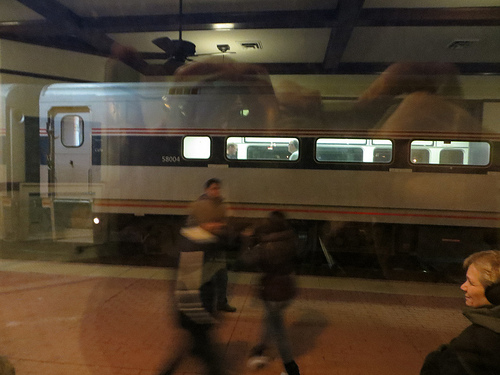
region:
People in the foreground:
[158, 170, 333, 372]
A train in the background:
[22, 75, 497, 276]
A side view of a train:
[27, 72, 497, 262]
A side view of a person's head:
[450, 245, 495, 315]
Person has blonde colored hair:
[445, 245, 495, 280]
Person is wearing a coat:
[401, 305, 496, 370]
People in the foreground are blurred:
[137, 176, 317, 371]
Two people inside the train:
[225, 137, 300, 162]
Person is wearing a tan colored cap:
[161, 190, 246, 242]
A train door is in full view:
[44, 104, 106, 211]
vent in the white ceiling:
[442, 34, 482, 60]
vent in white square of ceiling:
[145, 26, 315, 63]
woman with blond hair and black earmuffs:
[451, 248, 496, 318]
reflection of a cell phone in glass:
[152, 236, 232, 336]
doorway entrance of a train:
[41, 95, 106, 247]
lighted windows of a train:
[171, 113, 493, 177]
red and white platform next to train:
[17, 251, 472, 365]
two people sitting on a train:
[219, 134, 301, 165]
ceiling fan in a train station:
[114, 16, 244, 91]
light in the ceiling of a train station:
[198, 13, 250, 43]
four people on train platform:
[155, 164, 497, 359]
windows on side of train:
[177, 125, 479, 172]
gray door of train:
[47, 114, 89, 199]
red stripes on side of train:
[85, 118, 495, 226]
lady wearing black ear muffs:
[421, 250, 498, 370]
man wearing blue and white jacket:
[172, 180, 242, 370]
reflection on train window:
[42, 30, 492, 373]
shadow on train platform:
[247, 278, 334, 362]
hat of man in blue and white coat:
[180, 195, 219, 220]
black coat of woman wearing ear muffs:
[419, 319, 499, 373]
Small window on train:
[171, 126, 216, 166]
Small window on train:
[219, 129, 302, 168]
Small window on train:
[309, 133, 394, 173]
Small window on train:
[404, 126, 499, 175]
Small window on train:
[56, 115, 85, 149]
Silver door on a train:
[40, 102, 109, 246]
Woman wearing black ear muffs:
[446, 249, 498, 307]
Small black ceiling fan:
[120, 21, 216, 73]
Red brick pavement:
[45, 290, 80, 350]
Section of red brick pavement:
[352, 298, 373, 337]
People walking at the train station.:
[170, 173, 317, 374]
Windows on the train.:
[176, 132, 495, 177]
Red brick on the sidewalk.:
[7, 266, 170, 373]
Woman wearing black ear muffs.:
[445, 252, 499, 331]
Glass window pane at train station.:
[3, 14, 497, 373]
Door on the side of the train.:
[43, 103, 123, 288]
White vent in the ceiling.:
[446, 36, 482, 56]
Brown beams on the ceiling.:
[13, 8, 498, 35]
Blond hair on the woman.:
[452, 248, 498, 314]